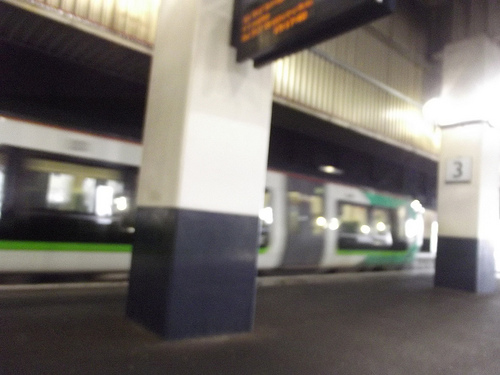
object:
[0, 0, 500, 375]
picture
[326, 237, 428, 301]
focused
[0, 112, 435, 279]
train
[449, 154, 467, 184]
number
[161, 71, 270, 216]
column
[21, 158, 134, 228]
windows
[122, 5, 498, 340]
columns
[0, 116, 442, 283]
subway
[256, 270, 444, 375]
plaform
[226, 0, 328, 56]
sign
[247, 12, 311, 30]
arrivals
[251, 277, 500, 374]
floor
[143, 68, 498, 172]
pillars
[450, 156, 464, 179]
3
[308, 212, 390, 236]
light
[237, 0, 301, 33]
letters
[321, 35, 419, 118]
shed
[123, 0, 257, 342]
post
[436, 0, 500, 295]
post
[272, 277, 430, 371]
cement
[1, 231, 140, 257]
stripe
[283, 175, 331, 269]
doors